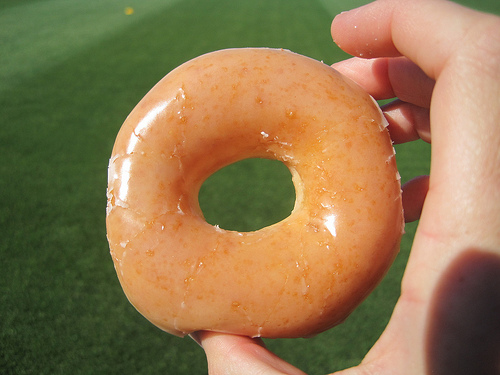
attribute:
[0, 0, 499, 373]
grass — fresh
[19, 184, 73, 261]
grass — fresh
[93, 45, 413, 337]
donut — glazed, held up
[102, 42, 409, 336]
doughnut — brown, round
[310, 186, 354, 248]
sugar coating — white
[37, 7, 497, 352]
vegetation — green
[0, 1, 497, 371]
vegetation — green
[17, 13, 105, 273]
vegetation — green